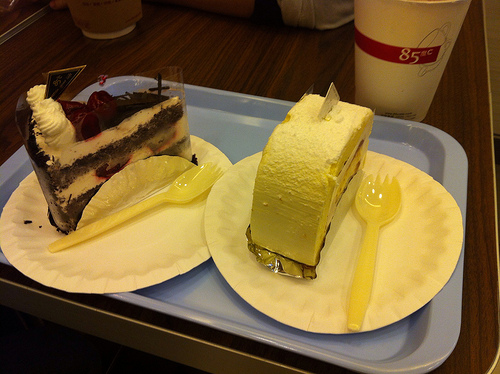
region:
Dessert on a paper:
[12, 67, 204, 190]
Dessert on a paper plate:
[10, 68, 184, 278]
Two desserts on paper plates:
[20, 59, 413, 332]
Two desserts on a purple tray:
[23, 72, 424, 311]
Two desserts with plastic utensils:
[18, 48, 421, 293]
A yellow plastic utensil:
[343, 157, 386, 338]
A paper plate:
[399, 156, 471, 347]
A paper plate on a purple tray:
[394, 124, 461, 371]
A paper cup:
[344, 29, 456, 133]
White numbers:
[384, 30, 444, 86]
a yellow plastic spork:
[341, 153, 407, 331]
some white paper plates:
[23, 106, 465, 360]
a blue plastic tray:
[10, 68, 475, 365]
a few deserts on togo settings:
[9, 11, 448, 348]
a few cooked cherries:
[48, 79, 137, 154]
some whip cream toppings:
[20, 78, 78, 150]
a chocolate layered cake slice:
[11, 67, 216, 247]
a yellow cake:
[236, 65, 372, 288]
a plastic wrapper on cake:
[8, 48, 223, 230]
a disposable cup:
[322, 13, 467, 143]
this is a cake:
[15, 78, 175, 220]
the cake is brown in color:
[25, 64, 175, 224]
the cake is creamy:
[28, 55, 178, 212]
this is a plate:
[103, 230, 185, 275]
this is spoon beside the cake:
[155, 163, 216, 212]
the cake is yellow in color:
[248, 108, 354, 261]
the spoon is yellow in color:
[352, 177, 405, 308]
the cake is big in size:
[16, 66, 181, 166]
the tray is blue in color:
[382, 128, 455, 147]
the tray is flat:
[195, 106, 260, 136]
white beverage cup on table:
[347, 0, 489, 125]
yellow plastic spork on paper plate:
[326, 168, 413, 336]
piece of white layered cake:
[239, 77, 377, 289]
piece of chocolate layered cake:
[13, 77, 205, 239]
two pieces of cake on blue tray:
[0, 60, 473, 372]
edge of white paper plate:
[47, 251, 219, 299]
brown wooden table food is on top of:
[157, 16, 337, 88]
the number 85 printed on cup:
[394, 44, 424, 68]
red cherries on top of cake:
[63, 87, 125, 145]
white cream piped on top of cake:
[22, 80, 80, 151]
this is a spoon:
[343, 163, 404, 322]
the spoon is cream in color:
[346, 166, 403, 328]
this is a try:
[11, 67, 452, 367]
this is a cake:
[15, 85, 380, 286]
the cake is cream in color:
[250, 74, 366, 269]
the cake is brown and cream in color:
[13, 71, 205, 191]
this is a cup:
[348, 0, 483, 120]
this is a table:
[458, 70, 498, 301]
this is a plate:
[203, 120, 473, 337]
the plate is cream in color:
[153, 126, 478, 331]